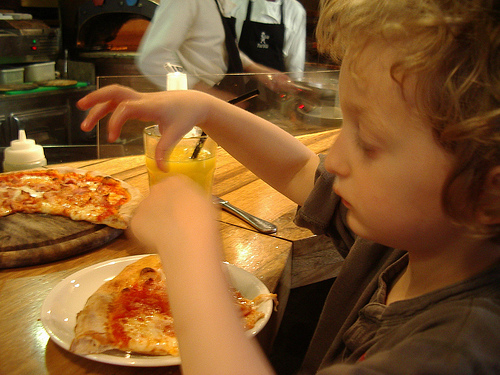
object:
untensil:
[208, 188, 278, 236]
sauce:
[114, 288, 157, 313]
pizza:
[0, 167, 145, 231]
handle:
[221, 199, 280, 236]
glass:
[29, 66, 106, 134]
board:
[0, 164, 134, 270]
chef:
[132, 0, 248, 111]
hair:
[314, 0, 500, 247]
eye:
[353, 130, 381, 161]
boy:
[72, 1, 500, 374]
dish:
[0, 166, 130, 269]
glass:
[144, 125, 219, 204]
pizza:
[66, 252, 279, 361]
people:
[229, 0, 307, 91]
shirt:
[222, 0, 309, 83]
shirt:
[134, 1, 236, 94]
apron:
[237, 0, 289, 75]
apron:
[212, 1, 251, 92]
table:
[1, 126, 352, 375]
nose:
[317, 138, 355, 175]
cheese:
[254, 290, 281, 306]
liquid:
[145, 148, 215, 204]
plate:
[38, 249, 275, 369]